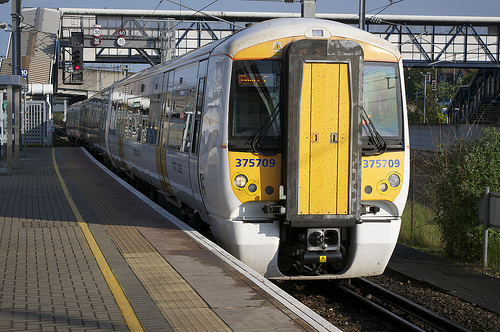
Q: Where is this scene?
A: Railway.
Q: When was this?
A: Daytime.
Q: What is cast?
A: Shadow.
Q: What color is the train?
A: Yellow and white.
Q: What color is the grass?
A: Green.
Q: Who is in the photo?
A: No one.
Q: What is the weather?
A: Sunny.